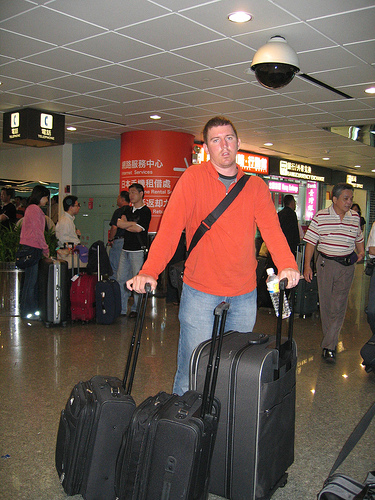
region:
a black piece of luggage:
[54, 282, 150, 497]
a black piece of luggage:
[112, 300, 228, 498]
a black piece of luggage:
[188, 274, 294, 499]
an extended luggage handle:
[121, 281, 151, 395]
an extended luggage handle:
[200, 299, 229, 414]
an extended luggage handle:
[276, 274, 296, 353]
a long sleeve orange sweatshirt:
[135, 159, 296, 294]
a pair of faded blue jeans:
[175, 280, 257, 401]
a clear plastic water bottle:
[261, 267, 292, 320]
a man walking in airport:
[301, 182, 366, 365]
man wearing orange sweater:
[122, 109, 332, 337]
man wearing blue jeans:
[158, 258, 263, 420]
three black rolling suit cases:
[50, 260, 311, 498]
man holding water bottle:
[254, 252, 309, 355]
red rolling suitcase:
[36, 239, 115, 342]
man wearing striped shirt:
[290, 167, 374, 278]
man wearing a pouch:
[313, 234, 374, 275]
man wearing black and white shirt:
[104, 175, 156, 270]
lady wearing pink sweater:
[14, 168, 76, 282]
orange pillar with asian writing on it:
[110, 123, 215, 268]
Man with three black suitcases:
[53, 114, 301, 497]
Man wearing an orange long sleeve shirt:
[123, 113, 300, 398]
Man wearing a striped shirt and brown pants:
[301, 181, 364, 364]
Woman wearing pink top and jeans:
[13, 183, 49, 322]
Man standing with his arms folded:
[115, 181, 151, 321]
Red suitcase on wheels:
[66, 245, 98, 326]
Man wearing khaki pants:
[53, 193, 85, 269]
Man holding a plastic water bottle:
[124, 113, 301, 398]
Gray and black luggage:
[313, 388, 373, 498]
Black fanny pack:
[316, 249, 358, 267]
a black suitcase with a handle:
[53, 282, 151, 498]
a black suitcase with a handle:
[113, 300, 230, 499]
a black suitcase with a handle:
[188, 277, 295, 498]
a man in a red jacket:
[127, 115, 300, 394]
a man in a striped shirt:
[302, 184, 365, 366]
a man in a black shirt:
[115, 181, 150, 320]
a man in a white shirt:
[52, 192, 85, 275]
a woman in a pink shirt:
[18, 184, 50, 320]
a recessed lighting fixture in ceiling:
[226, 11, 252, 22]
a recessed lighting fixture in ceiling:
[149, 113, 160, 122]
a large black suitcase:
[189, 274, 307, 495]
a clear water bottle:
[265, 266, 291, 319]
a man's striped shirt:
[303, 208, 365, 260]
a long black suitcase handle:
[105, 281, 154, 390]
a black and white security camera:
[248, 40, 299, 90]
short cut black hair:
[127, 182, 145, 200]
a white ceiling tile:
[84, 64, 152, 88]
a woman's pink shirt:
[20, 199, 51, 250]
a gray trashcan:
[4, 260, 22, 316]